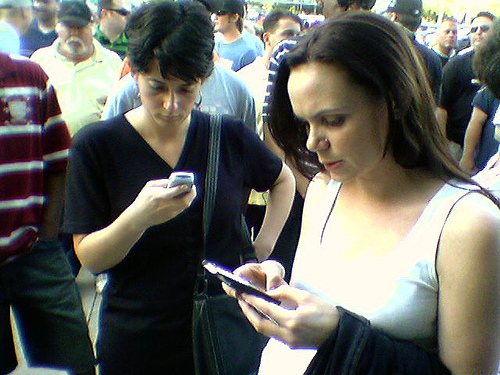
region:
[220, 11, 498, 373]
a woman looking at her phone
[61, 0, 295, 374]
a woman looking at her phone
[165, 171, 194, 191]
a telephone held by a woman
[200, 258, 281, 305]
a telephone held by a woman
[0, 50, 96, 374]
a man standing with his hand in a pocket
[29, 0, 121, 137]
a man wearing a black cap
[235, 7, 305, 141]
a man with a white shirt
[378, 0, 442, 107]
a man wearing a black cap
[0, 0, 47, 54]
a man wearing a cap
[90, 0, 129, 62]
a man wearing sunglasses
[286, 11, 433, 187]
Head of texting person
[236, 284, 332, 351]
Hand of texting person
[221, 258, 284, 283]
Hand of texting person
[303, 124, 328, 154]
Nose of texting person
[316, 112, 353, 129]
Eye of texting person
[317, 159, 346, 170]
Mouth of texting person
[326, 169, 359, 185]
Chin of texting person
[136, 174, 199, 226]
Hand of texting person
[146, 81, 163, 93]
Eye of texting person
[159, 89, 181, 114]
Nose of texting person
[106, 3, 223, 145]
woman with short dark hair and earrings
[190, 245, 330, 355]
cell phone being used by two hands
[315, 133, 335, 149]
mole on side of woman's nose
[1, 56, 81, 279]
burgundy and white striped shirt with logo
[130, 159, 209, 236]
woman holding old fashioned phone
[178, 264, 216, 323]
metal ring attaching handle to leather bag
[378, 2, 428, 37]
back of man's head wearing hat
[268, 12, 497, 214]
long dark brown hair on woman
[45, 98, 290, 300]
woman's black v neck tee shirt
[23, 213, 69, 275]
man has his hand in pocket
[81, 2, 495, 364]
two women with dark hair using phones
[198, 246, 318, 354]
shiny cellular phone in two hands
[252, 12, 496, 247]
woman with dark straight long hair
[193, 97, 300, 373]
black leather shoulder bag carried by woman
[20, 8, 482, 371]
crowd of people standing outside together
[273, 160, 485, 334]
woman is wearing a white tank top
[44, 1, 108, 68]
man with white facial hair with black hat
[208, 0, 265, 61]
man with sunglasses wearing blue shirt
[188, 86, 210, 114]
hoop earring hanging off of woman's ear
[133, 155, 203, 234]
woman holding old style cell phone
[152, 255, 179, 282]
black fabric on shirt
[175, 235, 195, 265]
black fabric on shirt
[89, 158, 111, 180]
black fabric on shirt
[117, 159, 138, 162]
black fabric on shirt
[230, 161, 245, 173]
black fabric on shirt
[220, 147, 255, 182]
black fabric on shirt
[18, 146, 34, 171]
black fabric on shirt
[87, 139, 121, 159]
black fabric on shirt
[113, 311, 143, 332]
black fabric on shirt